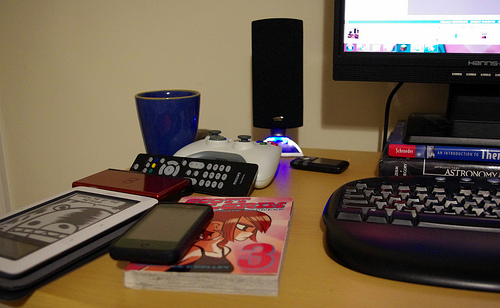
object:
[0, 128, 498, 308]
desk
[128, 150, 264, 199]
remote control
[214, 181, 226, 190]
buttons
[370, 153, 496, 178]
book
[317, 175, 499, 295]
keyboard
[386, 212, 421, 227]
keys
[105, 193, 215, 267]
cell phone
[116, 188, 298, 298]
book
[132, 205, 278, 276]
girl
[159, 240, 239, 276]
tank top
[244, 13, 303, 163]
speaker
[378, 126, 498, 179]
stack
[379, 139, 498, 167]
books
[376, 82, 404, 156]
wiring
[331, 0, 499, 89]
monitor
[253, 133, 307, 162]
base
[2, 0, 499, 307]
items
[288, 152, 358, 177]
cellphone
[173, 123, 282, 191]
game controller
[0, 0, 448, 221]
wall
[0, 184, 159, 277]
computer tablet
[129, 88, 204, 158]
coffee cup